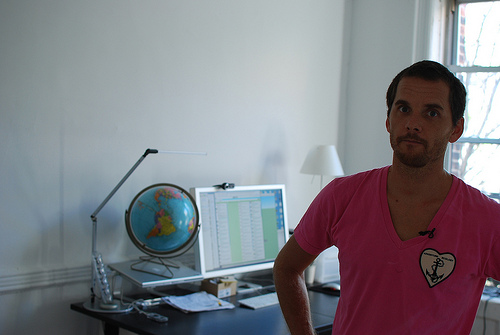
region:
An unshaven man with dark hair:
[365, 54, 470, 169]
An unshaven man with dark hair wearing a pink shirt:
[342, 47, 463, 269]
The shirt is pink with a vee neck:
[341, 161, 486, 321]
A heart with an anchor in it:
[414, 246, 460, 291]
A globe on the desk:
[124, 169, 211, 295]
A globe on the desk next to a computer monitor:
[125, 174, 282, 303]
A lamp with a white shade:
[303, 124, 350, 202]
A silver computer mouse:
[319, 277, 342, 297]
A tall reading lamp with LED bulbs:
[78, 126, 211, 320]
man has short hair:
[371, 65, 485, 157]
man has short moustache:
[387, 117, 459, 159]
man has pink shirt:
[304, 150, 481, 315]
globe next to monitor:
[106, 175, 169, 260]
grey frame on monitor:
[188, 185, 295, 273]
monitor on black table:
[187, 184, 297, 334]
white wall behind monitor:
[12, 64, 262, 161]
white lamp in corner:
[291, 138, 363, 206]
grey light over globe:
[81, 127, 198, 299]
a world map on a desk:
[119, 179, 208, 284]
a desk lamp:
[76, 135, 203, 320]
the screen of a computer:
[193, 178, 295, 283]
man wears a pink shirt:
[266, 52, 498, 334]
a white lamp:
[294, 132, 350, 200]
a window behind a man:
[359, 2, 499, 300]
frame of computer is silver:
[188, 178, 299, 286]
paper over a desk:
[154, 285, 236, 320]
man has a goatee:
[334, 40, 499, 235]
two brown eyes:
[393, 94, 442, 124]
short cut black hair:
[387, 58, 465, 128]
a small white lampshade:
[297, 143, 344, 181]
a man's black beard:
[392, 133, 432, 165]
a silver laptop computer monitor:
[191, 185, 290, 278]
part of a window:
[440, 4, 498, 196]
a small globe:
[125, 180, 200, 264]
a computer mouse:
[320, 275, 341, 295]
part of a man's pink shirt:
[291, 165, 498, 333]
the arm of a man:
[267, 180, 337, 334]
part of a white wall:
[0, 0, 345, 110]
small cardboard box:
[198, 275, 237, 296]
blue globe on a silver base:
[126, 181, 203, 277]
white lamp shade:
[300, 143, 343, 177]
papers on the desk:
[162, 290, 236, 311]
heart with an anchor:
[418, 247, 456, 287]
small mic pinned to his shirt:
[418, 225, 437, 239]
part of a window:
[442, 3, 499, 201]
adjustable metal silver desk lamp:
[81, 148, 208, 315]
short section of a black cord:
[480, 296, 494, 333]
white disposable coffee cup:
[306, 264, 316, 282]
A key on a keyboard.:
[268, 296, 270, 299]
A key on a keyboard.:
[258, 296, 262, 300]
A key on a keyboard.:
[268, 293, 275, 295]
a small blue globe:
[119, 184, 201, 275]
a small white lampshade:
[302, 135, 346, 177]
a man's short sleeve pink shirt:
[293, 163, 498, 333]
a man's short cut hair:
[385, 59, 465, 133]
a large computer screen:
[192, 183, 290, 276]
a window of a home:
[439, 3, 499, 190]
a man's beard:
[392, 135, 431, 165]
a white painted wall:
[345, 0, 417, 172]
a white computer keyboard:
[235, 290, 282, 307]